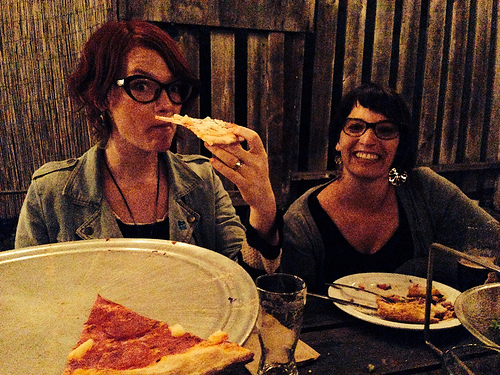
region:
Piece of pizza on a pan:
[51, 290, 232, 372]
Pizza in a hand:
[154, 100, 308, 182]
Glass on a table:
[242, 250, 367, 372]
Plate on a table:
[324, 250, 498, 319]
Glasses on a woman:
[78, 58, 216, 115]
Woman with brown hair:
[314, 74, 437, 186]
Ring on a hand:
[213, 133, 278, 185]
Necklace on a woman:
[72, 132, 249, 205]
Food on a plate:
[344, 272, 454, 318]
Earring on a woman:
[374, 154, 452, 191]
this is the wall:
[344, 11, 464, 75]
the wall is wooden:
[333, 19, 451, 70]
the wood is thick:
[328, 5, 436, 72]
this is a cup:
[249, 273, 315, 371]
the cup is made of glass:
[253, 272, 313, 364]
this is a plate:
[351, 269, 371, 286]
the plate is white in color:
[347, 305, 364, 316]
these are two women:
[17, 18, 498, 338]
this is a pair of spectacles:
[103, 68, 196, 108]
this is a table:
[336, 348, 363, 370]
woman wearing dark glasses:
[91, 60, 204, 187]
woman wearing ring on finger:
[220, 151, 252, 176]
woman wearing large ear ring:
[383, 158, 425, 203]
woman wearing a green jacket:
[5, 146, 260, 269]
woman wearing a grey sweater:
[285, 157, 498, 313]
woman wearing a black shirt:
[285, 158, 465, 324]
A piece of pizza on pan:
[51, 280, 268, 373]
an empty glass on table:
[251, 260, 317, 373]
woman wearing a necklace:
[93, 142, 184, 238]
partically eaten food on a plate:
[318, 261, 480, 351]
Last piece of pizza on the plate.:
[54, 280, 260, 373]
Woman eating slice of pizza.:
[20, 15, 297, 306]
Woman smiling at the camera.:
[317, 76, 424, 211]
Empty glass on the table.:
[245, 258, 313, 373]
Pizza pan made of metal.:
[2, 240, 264, 374]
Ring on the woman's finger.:
[225, 152, 253, 180]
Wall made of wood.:
[282, 1, 494, 78]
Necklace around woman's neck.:
[92, 145, 186, 230]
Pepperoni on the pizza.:
[97, 314, 152, 339]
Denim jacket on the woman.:
[17, 130, 288, 309]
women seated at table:
[22, 20, 497, 374]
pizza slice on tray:
[0, 235, 257, 372]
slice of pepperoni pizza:
[66, 295, 251, 372]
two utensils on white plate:
[307, 270, 463, 328]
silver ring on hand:
[203, 125, 270, 207]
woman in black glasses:
[77, 19, 203, 152]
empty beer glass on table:
[253, 273, 332, 373]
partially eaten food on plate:
[330, 269, 469, 327]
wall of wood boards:
[187, 1, 496, 167]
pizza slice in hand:
[155, 112, 269, 200]